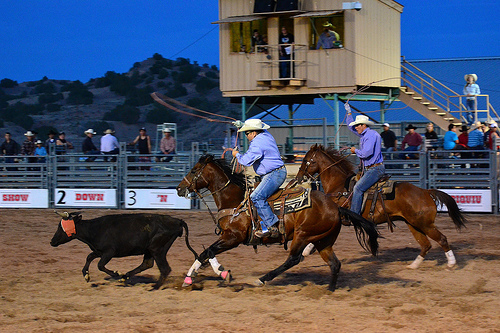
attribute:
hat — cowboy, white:
[345, 112, 375, 127]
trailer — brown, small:
[200, 0, 499, 148]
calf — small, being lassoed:
[41, 205, 206, 292]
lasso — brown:
[149, 89, 242, 126]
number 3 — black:
[124, 188, 137, 206]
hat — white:
[350, 113, 372, 133]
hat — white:
[226, 114, 273, 139]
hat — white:
[80, 126, 95, 138]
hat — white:
[21, 129, 35, 139]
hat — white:
[162, 125, 171, 135]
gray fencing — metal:
[0, 135, 498, 213]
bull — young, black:
[51, 214, 193, 296]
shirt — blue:
[233, 129, 285, 179]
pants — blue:
[249, 167, 288, 224]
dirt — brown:
[178, 280, 331, 331]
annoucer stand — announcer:
[209, 5, 426, 106]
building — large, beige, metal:
[213, 0, 406, 100]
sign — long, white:
[55, 187, 190, 207]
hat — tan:
[104, 126, 116, 133]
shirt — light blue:
[100, 133, 112, 152]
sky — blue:
[408, 7, 488, 48]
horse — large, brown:
[168, 157, 385, 299]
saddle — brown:
[246, 168, 314, 217]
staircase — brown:
[400, 57, 499, 144]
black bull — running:
[41, 200, 200, 289]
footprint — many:
[440, 295, 474, 312]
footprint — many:
[384, 300, 430, 322]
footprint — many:
[349, 292, 388, 310]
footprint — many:
[297, 287, 349, 308]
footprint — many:
[465, 246, 498, 271]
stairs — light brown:
[400, 90, 447, 123]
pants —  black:
[102, 147, 129, 161]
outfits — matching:
[223, 96, 397, 241]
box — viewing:
[214, 0, 410, 103]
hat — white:
[240, 111, 270, 132]